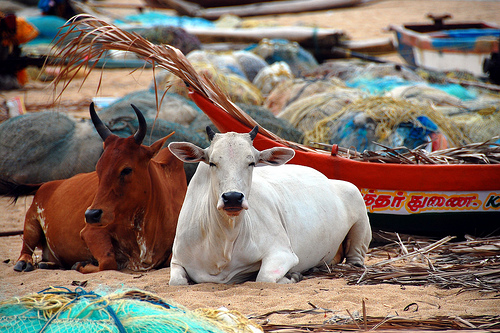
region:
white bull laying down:
[177, 120, 377, 292]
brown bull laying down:
[21, 109, 208, 284]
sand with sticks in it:
[171, 271, 463, 331]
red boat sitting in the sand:
[141, 44, 497, 244]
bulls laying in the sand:
[49, 96, 371, 298]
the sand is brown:
[231, 270, 368, 331]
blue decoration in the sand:
[14, 258, 207, 331]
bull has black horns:
[84, 97, 173, 152]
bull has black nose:
[216, 185, 255, 217]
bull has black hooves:
[13, 257, 39, 274]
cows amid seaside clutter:
[18, 15, 488, 321]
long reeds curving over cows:
[10, 6, 370, 286]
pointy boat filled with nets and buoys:
[166, 46, 491, 236]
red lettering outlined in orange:
[356, 188, 481, 211]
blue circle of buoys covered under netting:
[5, 275, 220, 325]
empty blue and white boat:
[386, 10, 492, 75]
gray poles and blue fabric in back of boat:
[15, 6, 386, 61]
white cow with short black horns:
[160, 121, 370, 286]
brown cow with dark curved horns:
[10, 95, 185, 275]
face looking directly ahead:
[165, 121, 295, 226]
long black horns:
[82, 97, 157, 144]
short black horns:
[203, 118, 260, 141]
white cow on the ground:
[170, 130, 367, 276]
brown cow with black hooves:
[15, 115, 177, 272]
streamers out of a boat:
[42, 4, 212, 89]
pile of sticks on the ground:
[267, 207, 498, 332]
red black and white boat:
[174, 78, 499, 232]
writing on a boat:
[345, 183, 495, 215]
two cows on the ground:
[5, 108, 383, 278]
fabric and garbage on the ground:
[14, 2, 488, 332]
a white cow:
[166, 127, 373, 282]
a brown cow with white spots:
[9, 101, 186, 278]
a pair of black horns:
[87, 100, 147, 144]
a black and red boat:
[183, 68, 498, 238]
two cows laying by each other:
[13, 100, 370, 285]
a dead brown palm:
[36, 13, 226, 120]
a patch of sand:
[308, 280, 403, 314]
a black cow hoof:
[12, 257, 33, 274]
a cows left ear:
[258, 147, 293, 166]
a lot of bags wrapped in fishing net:
[120, 39, 487, 144]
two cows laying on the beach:
[9, 115, 380, 279]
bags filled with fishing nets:
[342, 69, 437, 136]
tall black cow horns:
[94, 98, 153, 148]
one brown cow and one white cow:
[20, 112, 383, 269]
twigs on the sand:
[382, 220, 490, 308]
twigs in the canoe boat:
[386, 131, 491, 176]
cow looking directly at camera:
[180, 111, 315, 228]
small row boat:
[388, 8, 493, 72]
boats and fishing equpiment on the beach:
[17, 0, 480, 323]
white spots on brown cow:
[33, 190, 65, 246]